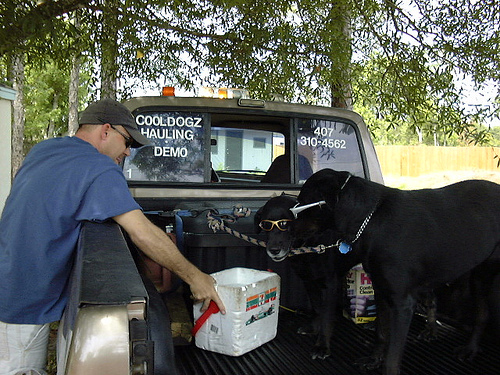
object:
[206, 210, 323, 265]
leash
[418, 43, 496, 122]
sky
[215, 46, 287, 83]
leaves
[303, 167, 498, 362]
dog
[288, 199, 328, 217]
sunglasses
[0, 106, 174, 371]
man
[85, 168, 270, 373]
cab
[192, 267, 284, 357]
cooler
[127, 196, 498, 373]
bed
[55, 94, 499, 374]
truck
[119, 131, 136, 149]
sunglasses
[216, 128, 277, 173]
house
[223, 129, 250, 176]
door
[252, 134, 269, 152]
window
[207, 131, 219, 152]
window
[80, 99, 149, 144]
hat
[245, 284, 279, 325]
sticker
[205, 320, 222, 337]
sticker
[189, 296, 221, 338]
handle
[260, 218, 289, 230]
glasses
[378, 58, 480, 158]
tree fence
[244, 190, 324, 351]
dog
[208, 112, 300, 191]
window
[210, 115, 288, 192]
rear window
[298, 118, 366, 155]
number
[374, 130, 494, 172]
fence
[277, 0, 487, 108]
tree